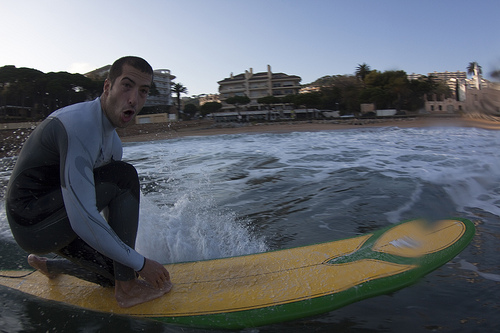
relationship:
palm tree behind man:
[354, 61, 371, 84] [8, 55, 165, 307]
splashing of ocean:
[136, 170, 282, 263] [112, 126, 500, 232]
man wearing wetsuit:
[8, 55, 165, 307] [4, 100, 165, 280]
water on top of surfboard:
[173, 264, 278, 308] [6, 210, 484, 330]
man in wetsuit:
[8, 55, 165, 307] [4, 100, 165, 280]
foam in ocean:
[261, 140, 490, 176] [112, 126, 500, 232]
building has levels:
[209, 70, 304, 117] [218, 78, 295, 91]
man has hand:
[8, 55, 165, 307] [140, 254, 179, 286]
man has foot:
[8, 55, 165, 307] [111, 278, 174, 305]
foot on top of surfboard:
[111, 278, 174, 305] [6, 210, 484, 330]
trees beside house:
[326, 78, 439, 103] [209, 70, 304, 117]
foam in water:
[261, 140, 490, 176] [173, 264, 278, 308]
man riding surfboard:
[8, 55, 165, 307] [6, 210, 484, 330]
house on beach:
[209, 70, 304, 117] [125, 111, 485, 137]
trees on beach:
[326, 78, 439, 103] [125, 111, 485, 137]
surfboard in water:
[6, 210, 484, 330] [173, 264, 278, 308]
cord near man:
[2, 270, 35, 280] [8, 55, 165, 307]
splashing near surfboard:
[136, 170, 282, 263] [6, 210, 484, 330]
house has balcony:
[209, 70, 304, 117] [222, 89, 296, 95]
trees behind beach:
[326, 78, 439, 103] [125, 111, 485, 137]